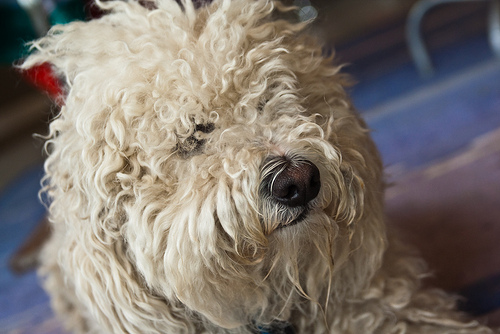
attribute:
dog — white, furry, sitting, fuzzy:
[17, 0, 409, 333]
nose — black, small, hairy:
[268, 159, 323, 207]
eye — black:
[175, 113, 218, 156]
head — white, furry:
[15, 0, 398, 331]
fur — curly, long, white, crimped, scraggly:
[14, 2, 493, 334]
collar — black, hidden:
[136, 279, 325, 333]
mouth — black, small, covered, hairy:
[264, 208, 316, 234]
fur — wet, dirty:
[224, 200, 361, 313]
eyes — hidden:
[171, 93, 287, 159]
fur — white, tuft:
[17, 0, 390, 327]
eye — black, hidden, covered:
[255, 94, 275, 113]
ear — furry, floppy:
[51, 70, 138, 196]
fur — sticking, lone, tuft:
[18, 0, 315, 83]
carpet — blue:
[2, 70, 497, 332]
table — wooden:
[315, 0, 490, 81]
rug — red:
[378, 140, 497, 326]